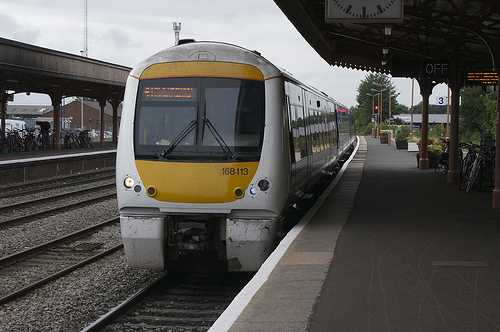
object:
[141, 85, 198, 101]
marquee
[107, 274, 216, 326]
train tracks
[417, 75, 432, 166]
column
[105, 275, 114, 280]
gravel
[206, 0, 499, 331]
station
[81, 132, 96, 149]
bicycles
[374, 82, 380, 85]
street lights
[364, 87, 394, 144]
row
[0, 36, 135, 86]
canopy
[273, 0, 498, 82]
canopy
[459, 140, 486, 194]
bicycle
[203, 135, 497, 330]
platform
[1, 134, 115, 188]
platform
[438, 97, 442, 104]
number 3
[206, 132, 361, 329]
line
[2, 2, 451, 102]
overcast sky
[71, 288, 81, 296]
gravel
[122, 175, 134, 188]
headlight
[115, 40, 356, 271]
train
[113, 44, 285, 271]
front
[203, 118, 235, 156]
wipers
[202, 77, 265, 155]
window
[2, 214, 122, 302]
tracks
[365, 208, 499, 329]
scratches